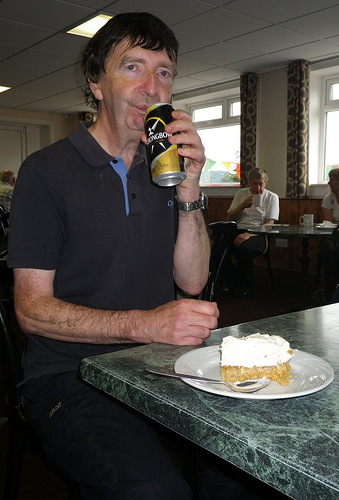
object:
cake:
[216, 327, 295, 388]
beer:
[138, 100, 190, 191]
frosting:
[215, 329, 296, 368]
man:
[221, 161, 281, 248]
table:
[79, 293, 338, 495]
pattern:
[295, 115, 308, 137]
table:
[258, 212, 337, 241]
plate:
[171, 336, 337, 405]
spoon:
[140, 359, 275, 399]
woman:
[317, 168, 337, 226]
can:
[138, 98, 189, 194]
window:
[192, 125, 248, 194]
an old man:
[8, 8, 241, 499]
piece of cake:
[216, 321, 298, 390]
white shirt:
[221, 184, 282, 238]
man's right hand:
[150, 289, 221, 350]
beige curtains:
[256, 62, 288, 201]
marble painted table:
[80, 303, 339, 499]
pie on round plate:
[171, 319, 336, 411]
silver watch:
[162, 194, 215, 218]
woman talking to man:
[216, 164, 338, 287]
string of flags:
[200, 155, 246, 176]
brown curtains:
[282, 60, 311, 199]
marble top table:
[301, 311, 337, 349]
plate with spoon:
[139, 328, 333, 410]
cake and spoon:
[136, 331, 294, 399]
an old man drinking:
[6, 11, 256, 499]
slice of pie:
[317, 215, 338, 227]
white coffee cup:
[245, 191, 262, 210]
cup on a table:
[299, 211, 315, 236]